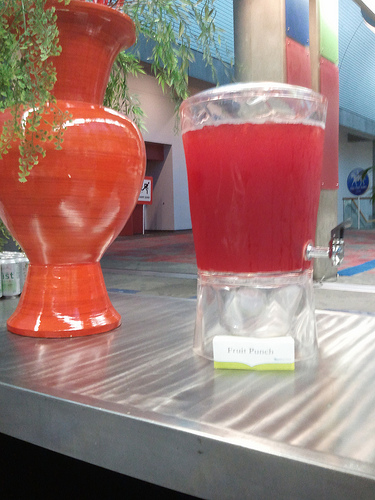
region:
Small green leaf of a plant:
[36, 44, 51, 55]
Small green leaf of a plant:
[42, 65, 58, 81]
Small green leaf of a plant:
[11, 168, 34, 182]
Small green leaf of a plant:
[25, 149, 42, 170]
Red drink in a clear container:
[175, 68, 334, 378]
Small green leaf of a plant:
[145, 55, 157, 75]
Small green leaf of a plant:
[152, 62, 169, 87]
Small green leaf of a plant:
[165, 77, 192, 101]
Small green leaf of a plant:
[201, 12, 218, 32]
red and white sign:
[135, 177, 152, 203]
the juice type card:
[212, 335, 293, 369]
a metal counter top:
[2, 286, 370, 493]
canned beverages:
[0, 250, 26, 296]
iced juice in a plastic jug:
[180, 82, 346, 364]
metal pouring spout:
[306, 220, 351, 267]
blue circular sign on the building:
[346, 167, 368, 195]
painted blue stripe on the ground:
[339, 259, 374, 276]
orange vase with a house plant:
[1, 1, 146, 337]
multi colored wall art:
[286, 0, 337, 189]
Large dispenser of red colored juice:
[170, 77, 352, 375]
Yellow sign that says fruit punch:
[209, 330, 298, 373]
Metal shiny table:
[1, 270, 374, 498]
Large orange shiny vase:
[0, 0, 150, 345]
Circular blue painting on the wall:
[345, 164, 370, 197]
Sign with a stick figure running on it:
[135, 173, 153, 204]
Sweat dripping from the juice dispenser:
[180, 117, 327, 283]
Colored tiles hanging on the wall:
[280, 0, 342, 192]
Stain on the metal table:
[172, 431, 205, 457]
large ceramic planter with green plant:
[9, 7, 148, 347]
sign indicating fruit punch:
[200, 330, 300, 375]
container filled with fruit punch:
[193, 79, 344, 379]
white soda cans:
[0, 245, 38, 299]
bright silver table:
[2, 292, 367, 496]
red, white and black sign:
[133, 173, 161, 242]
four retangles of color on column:
[279, 0, 344, 197]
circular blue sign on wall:
[340, 164, 372, 207]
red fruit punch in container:
[190, 118, 328, 265]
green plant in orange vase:
[2, 1, 63, 167]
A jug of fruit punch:
[173, 70, 332, 373]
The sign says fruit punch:
[206, 324, 305, 373]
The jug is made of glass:
[173, 82, 339, 372]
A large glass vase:
[5, 19, 146, 344]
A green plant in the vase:
[4, 0, 219, 170]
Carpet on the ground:
[117, 230, 189, 291]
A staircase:
[338, 189, 374, 232]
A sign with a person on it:
[140, 174, 160, 232]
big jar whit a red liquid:
[186, 88, 327, 307]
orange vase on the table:
[31, 21, 125, 346]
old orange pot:
[55, 6, 104, 178]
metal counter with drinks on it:
[18, 361, 265, 448]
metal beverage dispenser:
[329, 226, 347, 265]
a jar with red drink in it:
[187, 91, 332, 379]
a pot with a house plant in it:
[4, 9, 150, 309]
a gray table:
[61, 329, 188, 417]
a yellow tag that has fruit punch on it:
[167, 318, 296, 387]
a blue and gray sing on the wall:
[328, 158, 368, 206]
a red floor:
[113, 223, 181, 276]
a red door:
[122, 196, 153, 241]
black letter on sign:
[225, 344, 234, 355]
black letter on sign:
[230, 347, 237, 353]